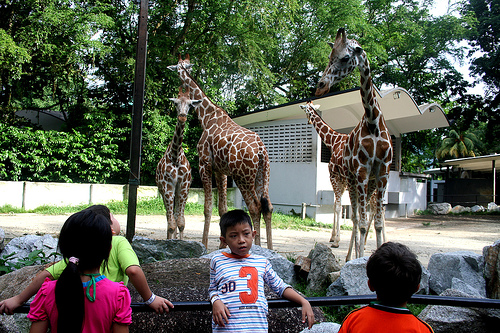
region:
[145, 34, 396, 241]
four giraffes standing together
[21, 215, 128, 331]
girl wearing pink shirt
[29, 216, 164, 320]
boy wearing green shirt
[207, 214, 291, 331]
boy wearing striped shirt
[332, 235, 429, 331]
boy wearing orange shirt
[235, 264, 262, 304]
number 3 on front of striped shirt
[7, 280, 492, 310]
black bar boy is leaning on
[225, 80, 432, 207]
white building behind giraffes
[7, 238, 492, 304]
rocks inside giraffes' environment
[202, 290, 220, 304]
white wristband on boy's arm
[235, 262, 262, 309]
#3 on front of boys shirt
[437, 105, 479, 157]
palm tree in the distance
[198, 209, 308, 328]
striped shirt on little boy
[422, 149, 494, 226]
Building to the right of photo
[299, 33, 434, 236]
two giraffes in the zoo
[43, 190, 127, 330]
little girl with dark hair and pony tail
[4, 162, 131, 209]
white fence in distance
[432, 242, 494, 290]
rock boulders by road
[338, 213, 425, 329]
little boy watching giraffe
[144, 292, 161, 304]
wristband on little boy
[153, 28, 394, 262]
four giraffes in an enclosure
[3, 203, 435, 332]
four children at the fence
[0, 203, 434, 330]
three kids looking at the giraffes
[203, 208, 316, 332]
one child looking away and bored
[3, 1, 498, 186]
trees behind the enclosure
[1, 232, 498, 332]
big rocks in front of fence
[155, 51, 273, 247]
mother and baby giraffe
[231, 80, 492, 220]
building on the other side of enclosure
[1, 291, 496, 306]
children are leaning on a black metal rail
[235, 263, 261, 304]
big orange 3 on boys shirt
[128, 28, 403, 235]
four giraffes on the ground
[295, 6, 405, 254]
two giraffes standing still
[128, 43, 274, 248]
two giraffes next to each other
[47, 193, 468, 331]
group of kids standing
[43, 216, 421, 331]
group of kids looking at giraffes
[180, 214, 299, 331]
kid leaning on pole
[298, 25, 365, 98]
large head of giraffe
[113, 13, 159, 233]
brown post on the ground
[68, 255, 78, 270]
hair tie on hair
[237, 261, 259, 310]
orange number three on front of kids shirt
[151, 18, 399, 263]
4 giraffes: 2 interested in park visitors, 2 not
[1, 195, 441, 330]
4 kids: 3 interested [very] in giraffes, 1 bored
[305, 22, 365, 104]
a critical expression above inward pointing horns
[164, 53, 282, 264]
the largest giraffe turns away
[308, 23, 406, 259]
the second largest giraffe considers, cynically, expectantly, park visitors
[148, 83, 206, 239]
smallest giraffe holds ears perpendicular to face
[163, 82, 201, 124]
smallest giraffe looks intrigued, expectant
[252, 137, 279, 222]
a long long tufted tail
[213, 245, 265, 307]
an orange '3', an orange collar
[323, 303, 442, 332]
an orange shirt, from the back